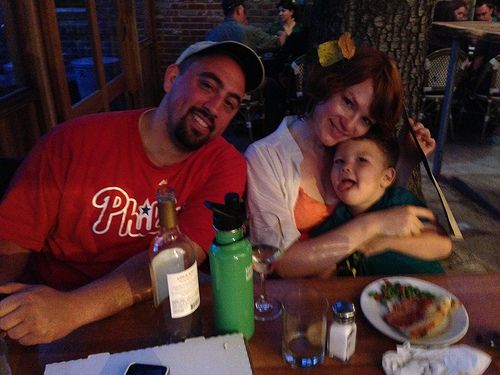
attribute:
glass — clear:
[239, 207, 288, 327]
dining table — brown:
[81, 240, 453, 373]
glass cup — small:
[280, 289, 325, 370]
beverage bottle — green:
[201, 205, 263, 341]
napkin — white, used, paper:
[369, 337, 486, 372]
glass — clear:
[278, 292, 327, 367]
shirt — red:
[8, 102, 253, 284]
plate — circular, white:
[360, 277, 469, 346]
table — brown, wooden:
[0, 265, 476, 372]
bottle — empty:
[121, 170, 209, 353]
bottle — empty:
[146, 175, 201, 342]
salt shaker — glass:
[325, 298, 359, 362]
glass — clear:
[276, 280, 333, 368]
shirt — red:
[16, 110, 252, 305]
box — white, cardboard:
[33, 316, 264, 375]